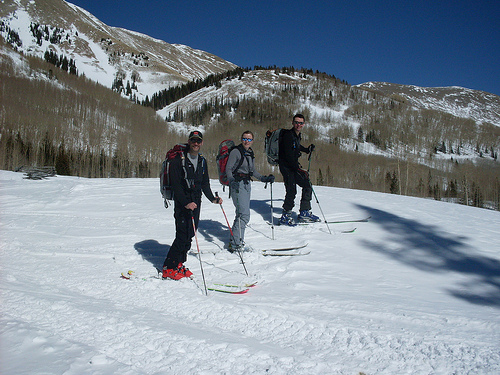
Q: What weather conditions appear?
A: It is clear.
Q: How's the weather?
A: It is clear.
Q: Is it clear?
A: Yes, it is clear.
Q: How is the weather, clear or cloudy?
A: It is clear.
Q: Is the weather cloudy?
A: No, it is clear.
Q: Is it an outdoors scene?
A: Yes, it is outdoors.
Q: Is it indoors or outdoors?
A: It is outdoors.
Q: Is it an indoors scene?
A: No, it is outdoors.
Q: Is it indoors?
A: No, it is outdoors.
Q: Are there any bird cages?
A: No, there are no bird cages.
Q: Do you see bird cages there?
A: No, there are no bird cages.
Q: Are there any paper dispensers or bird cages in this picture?
A: No, there are no bird cages or paper dispensers.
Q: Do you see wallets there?
A: No, there are no wallets.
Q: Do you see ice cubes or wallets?
A: No, there are no wallets or ice cubes.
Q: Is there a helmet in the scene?
A: No, there are no helmets.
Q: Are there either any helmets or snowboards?
A: No, there are no helmets or snowboards.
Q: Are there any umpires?
A: No, there are no umpires.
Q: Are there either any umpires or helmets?
A: No, there are no umpires or helmets.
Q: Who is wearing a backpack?
A: The man is wearing a backpack.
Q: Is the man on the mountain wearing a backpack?
A: Yes, the man is wearing a backpack.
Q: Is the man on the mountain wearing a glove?
A: No, the man is wearing a backpack.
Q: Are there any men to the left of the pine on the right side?
A: Yes, there is a man to the left of the pine tree.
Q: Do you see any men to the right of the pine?
A: No, the man is to the left of the pine.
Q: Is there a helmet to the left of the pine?
A: No, there is a man to the left of the pine.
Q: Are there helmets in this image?
A: No, there are no helmets.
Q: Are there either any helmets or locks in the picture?
A: No, there are no helmets or locks.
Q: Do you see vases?
A: No, there are no vases.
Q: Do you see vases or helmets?
A: No, there are no vases or helmets.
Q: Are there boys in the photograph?
A: No, there are no boys.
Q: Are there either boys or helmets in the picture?
A: No, there are no boys or helmets.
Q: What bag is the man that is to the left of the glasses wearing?
A: The man is wearing a backpack.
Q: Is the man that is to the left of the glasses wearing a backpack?
A: Yes, the man is wearing a backpack.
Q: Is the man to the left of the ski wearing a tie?
A: No, the man is wearing a backpack.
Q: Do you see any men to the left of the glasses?
A: Yes, there is a man to the left of the glasses.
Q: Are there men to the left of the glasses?
A: Yes, there is a man to the left of the glasses.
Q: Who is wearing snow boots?
A: The man is wearing snow boots.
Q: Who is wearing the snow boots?
A: The man is wearing snow boots.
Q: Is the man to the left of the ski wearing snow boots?
A: Yes, the man is wearing snow boots.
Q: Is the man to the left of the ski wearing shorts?
A: No, the man is wearing snow boots.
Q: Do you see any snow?
A: Yes, there is snow.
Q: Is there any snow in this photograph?
A: Yes, there is snow.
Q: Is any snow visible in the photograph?
A: Yes, there is snow.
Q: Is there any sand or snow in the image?
A: Yes, there is snow.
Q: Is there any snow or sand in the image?
A: Yes, there is snow.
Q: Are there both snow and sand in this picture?
A: No, there is snow but no sand.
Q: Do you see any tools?
A: No, there are no tools.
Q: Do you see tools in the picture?
A: No, there are no tools.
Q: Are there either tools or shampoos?
A: No, there are no tools or shampoos.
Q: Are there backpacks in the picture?
A: Yes, there is a backpack.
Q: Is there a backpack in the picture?
A: Yes, there is a backpack.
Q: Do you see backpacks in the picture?
A: Yes, there is a backpack.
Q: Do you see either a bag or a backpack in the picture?
A: Yes, there is a backpack.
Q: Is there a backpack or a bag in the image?
A: Yes, there is a backpack.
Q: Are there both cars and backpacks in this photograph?
A: No, there is a backpack but no cars.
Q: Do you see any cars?
A: No, there are no cars.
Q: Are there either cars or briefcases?
A: No, there are no cars or briefcases.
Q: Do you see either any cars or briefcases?
A: No, there are no cars or briefcases.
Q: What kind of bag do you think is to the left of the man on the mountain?
A: The bag is a backpack.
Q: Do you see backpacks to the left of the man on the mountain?
A: Yes, there is a backpack to the left of the man.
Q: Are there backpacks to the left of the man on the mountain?
A: Yes, there is a backpack to the left of the man.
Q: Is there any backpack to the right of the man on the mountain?
A: No, the backpack is to the left of the man.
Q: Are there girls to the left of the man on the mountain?
A: No, there is a backpack to the left of the man.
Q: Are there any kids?
A: No, there are no kids.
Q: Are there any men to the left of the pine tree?
A: Yes, there is a man to the left of the pine tree.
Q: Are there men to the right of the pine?
A: No, the man is to the left of the pine.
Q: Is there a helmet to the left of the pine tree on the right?
A: No, there is a man to the left of the pine tree.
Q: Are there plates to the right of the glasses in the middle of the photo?
A: No, there is a man to the right of the glasses.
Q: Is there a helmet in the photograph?
A: No, there are no helmets.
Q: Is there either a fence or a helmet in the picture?
A: No, there are no helmets or fences.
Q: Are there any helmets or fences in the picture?
A: No, there are no helmets or fences.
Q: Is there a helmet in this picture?
A: No, there are no helmets.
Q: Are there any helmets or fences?
A: No, there are no helmets or fences.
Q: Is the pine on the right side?
A: Yes, the pine is on the right of the image.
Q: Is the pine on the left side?
A: No, the pine is on the right of the image.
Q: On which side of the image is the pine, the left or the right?
A: The pine is on the right of the image.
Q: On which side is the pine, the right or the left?
A: The pine is on the right of the image.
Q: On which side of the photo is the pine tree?
A: The pine tree is on the right of the image.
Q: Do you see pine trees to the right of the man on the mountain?
A: Yes, there is a pine tree to the right of the man.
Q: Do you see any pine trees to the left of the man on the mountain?
A: No, the pine tree is to the right of the man.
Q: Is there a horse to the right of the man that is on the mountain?
A: No, there is a pine tree to the right of the man.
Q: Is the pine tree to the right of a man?
A: Yes, the pine tree is to the right of a man.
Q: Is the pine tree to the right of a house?
A: No, the pine tree is to the right of a man.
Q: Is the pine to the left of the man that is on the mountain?
A: No, the pine is to the right of the man.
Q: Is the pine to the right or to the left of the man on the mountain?
A: The pine is to the right of the man.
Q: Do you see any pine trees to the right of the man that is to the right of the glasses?
A: Yes, there is a pine tree to the right of the man.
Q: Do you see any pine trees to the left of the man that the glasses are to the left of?
A: No, the pine tree is to the right of the man.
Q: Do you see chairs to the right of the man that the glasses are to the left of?
A: No, there is a pine tree to the right of the man.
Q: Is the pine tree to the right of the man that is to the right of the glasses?
A: Yes, the pine tree is to the right of the man.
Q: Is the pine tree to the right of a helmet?
A: No, the pine tree is to the right of the man.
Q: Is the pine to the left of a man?
A: No, the pine is to the right of a man.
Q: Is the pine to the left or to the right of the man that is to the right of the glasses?
A: The pine is to the right of the man.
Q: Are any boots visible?
A: Yes, there are boots.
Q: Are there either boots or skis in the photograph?
A: Yes, there are boots.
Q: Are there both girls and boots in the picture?
A: No, there are boots but no girls.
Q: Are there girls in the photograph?
A: No, there are no girls.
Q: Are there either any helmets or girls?
A: No, there are no girls or helmets.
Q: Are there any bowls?
A: No, there are no bowls.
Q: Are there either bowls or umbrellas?
A: No, there are no bowls or umbrellas.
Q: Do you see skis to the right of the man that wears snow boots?
A: Yes, there is a ski to the right of the man.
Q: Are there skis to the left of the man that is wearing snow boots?
A: No, the ski is to the right of the man.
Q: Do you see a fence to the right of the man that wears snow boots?
A: No, there is a ski to the right of the man.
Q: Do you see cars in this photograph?
A: No, there are no cars.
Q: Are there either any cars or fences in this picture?
A: No, there are no cars or fences.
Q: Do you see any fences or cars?
A: No, there are no cars or fences.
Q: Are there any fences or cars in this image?
A: No, there are no cars or fences.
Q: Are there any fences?
A: No, there are no fences.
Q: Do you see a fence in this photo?
A: No, there are no fences.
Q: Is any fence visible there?
A: No, there are no fences.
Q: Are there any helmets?
A: No, there are no helmets.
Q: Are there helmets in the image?
A: No, there are no helmets.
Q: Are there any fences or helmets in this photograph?
A: No, there are no helmets or fences.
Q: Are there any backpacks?
A: Yes, there is a backpack.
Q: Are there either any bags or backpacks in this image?
A: Yes, there is a backpack.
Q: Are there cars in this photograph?
A: No, there are no cars.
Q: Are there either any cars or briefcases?
A: No, there are no cars or briefcases.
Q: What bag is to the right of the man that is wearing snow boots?
A: The bag is a backpack.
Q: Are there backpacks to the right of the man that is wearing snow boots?
A: Yes, there is a backpack to the right of the man.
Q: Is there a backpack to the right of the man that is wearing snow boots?
A: Yes, there is a backpack to the right of the man.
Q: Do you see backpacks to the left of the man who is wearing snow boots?
A: No, the backpack is to the right of the man.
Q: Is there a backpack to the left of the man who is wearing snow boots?
A: No, the backpack is to the right of the man.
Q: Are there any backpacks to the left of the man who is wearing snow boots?
A: No, the backpack is to the right of the man.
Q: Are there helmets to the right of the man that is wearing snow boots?
A: No, there is a backpack to the right of the man.